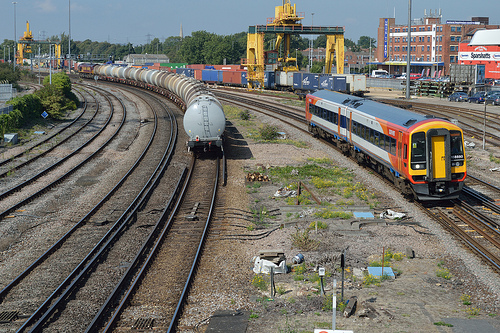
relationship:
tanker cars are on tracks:
[65, 62, 227, 147] [14, 77, 128, 215]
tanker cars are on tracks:
[65, 62, 227, 147] [424, 95, 498, 151]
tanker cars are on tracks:
[65, 62, 227, 147] [440, 207, 499, 272]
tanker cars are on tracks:
[65, 62, 227, 147] [9, 163, 250, 330]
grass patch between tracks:
[255, 160, 367, 212] [411, 196, 500, 272]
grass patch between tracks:
[255, 160, 367, 212] [0, 163, 227, 333]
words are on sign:
[425, 30, 498, 82] [449, 32, 496, 88]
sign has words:
[449, 32, 496, 88] [425, 30, 498, 82]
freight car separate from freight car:
[289, 70, 344, 95] [215, 63, 244, 85]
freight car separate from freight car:
[289, 70, 344, 95] [200, 60, 222, 85]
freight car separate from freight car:
[289, 70, 344, 95] [341, 72, 366, 90]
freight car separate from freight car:
[289, 70, 344, 95] [272, 67, 293, 87]